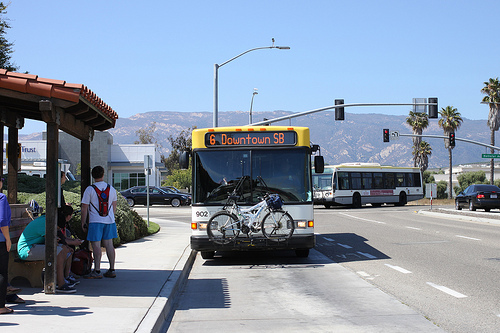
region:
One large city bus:
[182, 125, 341, 268]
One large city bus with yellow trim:
[180, 119, 328, 259]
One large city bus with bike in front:
[188, 129, 321, 260]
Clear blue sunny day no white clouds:
[320, 10, 420, 70]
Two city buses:
[173, 122, 429, 272]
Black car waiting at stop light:
[445, 171, 495, 206]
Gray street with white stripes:
[346, 208, 452, 309]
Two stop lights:
[370, 120, 466, 150]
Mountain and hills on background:
[355, 100, 423, 166]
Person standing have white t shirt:
[82, 165, 129, 290]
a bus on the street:
[187, 120, 329, 270]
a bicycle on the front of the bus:
[200, 182, 297, 248]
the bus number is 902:
[192, 205, 214, 220]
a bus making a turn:
[310, 152, 432, 214]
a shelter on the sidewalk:
[0, 57, 127, 298]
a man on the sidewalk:
[76, 161, 123, 278]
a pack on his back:
[90, 181, 116, 219]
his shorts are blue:
[85, 218, 116, 241]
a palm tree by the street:
[437, 107, 462, 202]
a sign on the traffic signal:
[481, 148, 498, 165]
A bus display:
[204, 130, 299, 147]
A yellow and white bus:
[186, 124, 326, 261]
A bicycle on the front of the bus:
[202, 187, 296, 255]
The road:
[125, 170, 497, 330]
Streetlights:
[203, 38, 291, 125]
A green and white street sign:
[478, 150, 498, 162]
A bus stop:
[0, 65, 119, 306]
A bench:
[5, 207, 73, 289]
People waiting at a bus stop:
[0, 153, 124, 320]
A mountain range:
[9, 109, 499, 191]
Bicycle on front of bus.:
[204, 184, 296, 247]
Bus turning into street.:
[313, 158, 431, 211]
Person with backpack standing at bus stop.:
[81, 164, 122, 278]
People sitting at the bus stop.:
[18, 199, 76, 291]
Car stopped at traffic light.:
[451, 180, 498, 210]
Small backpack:
[91, 179, 113, 219]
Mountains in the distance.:
[105, 108, 498, 165]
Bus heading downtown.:
[185, 122, 325, 268]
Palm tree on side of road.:
[438, 102, 463, 205]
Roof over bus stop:
[0, 69, 118, 130]